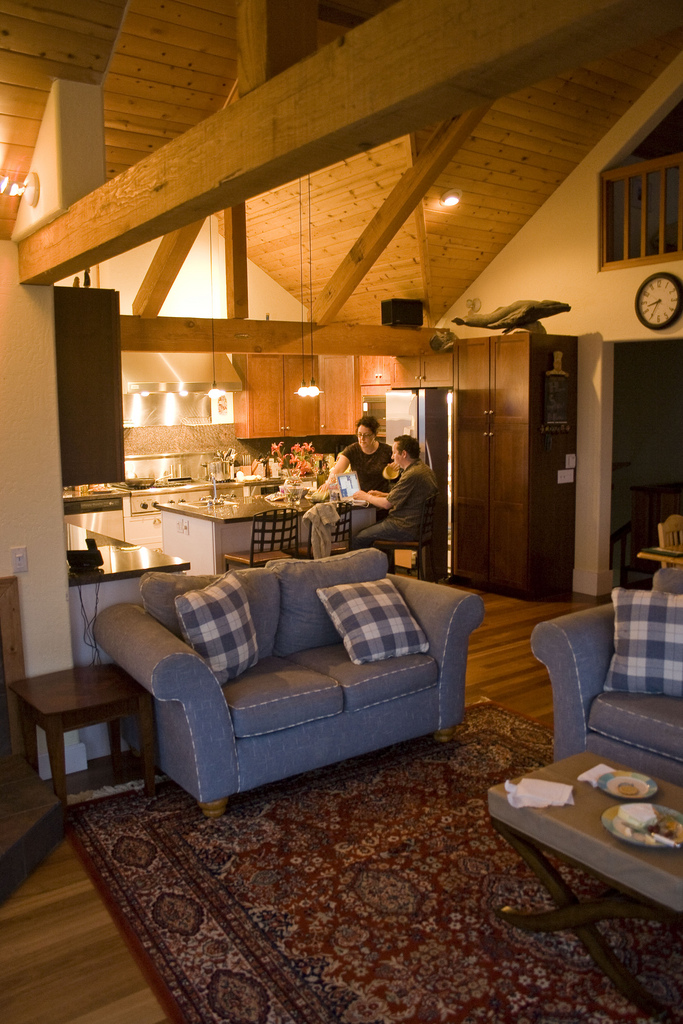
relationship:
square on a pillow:
[223, 602, 275, 636] [151, 565, 262, 694]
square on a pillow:
[201, 577, 228, 604] [173, 567, 264, 686]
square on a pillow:
[218, 569, 242, 596] [158, 552, 272, 693]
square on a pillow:
[181, 587, 208, 611] [163, 545, 319, 731]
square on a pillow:
[330, 592, 359, 624] [300, 569, 436, 668]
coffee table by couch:
[488, 721, 677, 899] [544, 579, 681, 732]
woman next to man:
[343, 404, 380, 502] [373, 424, 459, 589]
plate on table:
[597, 769, 659, 799] [445, 745, 651, 978]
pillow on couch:
[316, 578, 430, 665] [129, 517, 504, 904]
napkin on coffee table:
[504, 778, 575, 809] [488, 751, 683, 1023]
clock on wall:
[620, 239, 662, 378] [421, 181, 628, 633]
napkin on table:
[484, 756, 588, 831] [426, 687, 650, 924]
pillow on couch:
[324, 547, 477, 697] [102, 506, 503, 821]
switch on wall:
[12, 531, 62, 611] [1, 290, 190, 771]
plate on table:
[571, 722, 657, 810] [438, 701, 647, 949]